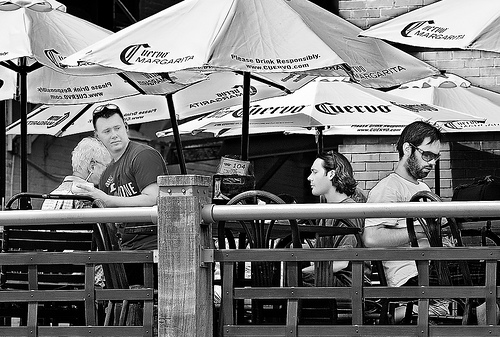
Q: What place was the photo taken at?
A: It was taken at the cafe.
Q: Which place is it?
A: It is a cafe.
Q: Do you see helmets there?
A: No, there are no helmets.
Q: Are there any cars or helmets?
A: No, there are no helmets or cars.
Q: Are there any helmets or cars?
A: No, there are no helmets or cars.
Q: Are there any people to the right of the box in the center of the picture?
A: Yes, there is a person to the right of the box.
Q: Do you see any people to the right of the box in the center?
A: Yes, there is a person to the right of the box.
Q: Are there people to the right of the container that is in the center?
A: Yes, there is a person to the right of the box.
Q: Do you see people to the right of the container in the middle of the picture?
A: Yes, there is a person to the right of the box.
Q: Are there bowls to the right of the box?
A: No, there is a person to the right of the box.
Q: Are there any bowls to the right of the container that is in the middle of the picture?
A: No, there is a person to the right of the box.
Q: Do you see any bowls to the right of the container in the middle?
A: No, there is a person to the right of the box.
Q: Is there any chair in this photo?
A: Yes, there is a chair.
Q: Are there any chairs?
A: Yes, there is a chair.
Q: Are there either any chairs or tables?
A: Yes, there is a chair.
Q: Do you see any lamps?
A: No, there are no lamps.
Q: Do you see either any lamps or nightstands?
A: No, there are no lamps or nightstands.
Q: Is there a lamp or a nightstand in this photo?
A: No, there are no lamps or nightstands.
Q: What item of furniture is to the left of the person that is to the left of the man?
A: The piece of furniture is a chair.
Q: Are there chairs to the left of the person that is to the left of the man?
A: Yes, there is a chair to the left of the person.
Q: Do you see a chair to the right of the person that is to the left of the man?
A: No, the chair is to the left of the person.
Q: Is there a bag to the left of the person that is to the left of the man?
A: No, there is a chair to the left of the person.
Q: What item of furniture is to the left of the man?
A: The piece of furniture is a chair.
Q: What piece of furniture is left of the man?
A: The piece of furniture is a chair.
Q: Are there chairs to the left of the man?
A: Yes, there is a chair to the left of the man.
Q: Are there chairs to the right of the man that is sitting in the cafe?
A: No, the chair is to the left of the man.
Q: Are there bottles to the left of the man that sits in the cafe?
A: No, there is a chair to the left of the man.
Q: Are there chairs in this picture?
A: Yes, there is a chair.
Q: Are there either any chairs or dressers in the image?
A: Yes, there is a chair.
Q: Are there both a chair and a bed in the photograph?
A: No, there is a chair but no beds.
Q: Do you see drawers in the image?
A: No, there are no drawers.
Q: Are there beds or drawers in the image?
A: No, there are no drawers or beds.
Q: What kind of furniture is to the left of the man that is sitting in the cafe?
A: The piece of furniture is a chair.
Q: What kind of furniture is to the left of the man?
A: The piece of furniture is a chair.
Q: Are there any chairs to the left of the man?
A: Yes, there is a chair to the left of the man.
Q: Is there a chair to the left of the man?
A: Yes, there is a chair to the left of the man.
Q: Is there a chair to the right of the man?
A: No, the chair is to the left of the man.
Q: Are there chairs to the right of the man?
A: No, the chair is to the left of the man.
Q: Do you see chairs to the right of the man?
A: No, the chair is to the left of the man.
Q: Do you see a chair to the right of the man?
A: No, the chair is to the left of the man.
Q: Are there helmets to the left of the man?
A: No, there is a chair to the left of the man.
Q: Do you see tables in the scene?
A: Yes, there is a table.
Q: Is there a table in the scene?
A: Yes, there is a table.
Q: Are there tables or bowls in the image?
A: Yes, there is a table.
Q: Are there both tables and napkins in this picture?
A: No, there is a table but no napkins.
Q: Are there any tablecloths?
A: No, there are no tablecloths.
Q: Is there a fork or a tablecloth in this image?
A: No, there are no tablecloths or forks.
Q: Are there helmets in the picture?
A: No, there are no helmets.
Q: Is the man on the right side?
A: Yes, the man is on the right of the image.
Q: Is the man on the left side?
A: No, the man is on the right of the image.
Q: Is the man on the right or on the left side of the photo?
A: The man is on the right of the image.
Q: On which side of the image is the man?
A: The man is on the right of the image.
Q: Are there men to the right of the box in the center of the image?
A: Yes, there is a man to the right of the box.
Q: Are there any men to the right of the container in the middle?
A: Yes, there is a man to the right of the box.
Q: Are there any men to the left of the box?
A: No, the man is to the right of the box.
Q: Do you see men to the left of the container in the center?
A: No, the man is to the right of the box.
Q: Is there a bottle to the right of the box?
A: No, there is a man to the right of the box.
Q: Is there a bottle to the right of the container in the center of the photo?
A: No, there is a man to the right of the box.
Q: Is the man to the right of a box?
A: Yes, the man is to the right of a box.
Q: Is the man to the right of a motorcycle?
A: No, the man is to the right of a box.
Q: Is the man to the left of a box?
A: No, the man is to the right of a box.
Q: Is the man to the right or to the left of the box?
A: The man is to the right of the box.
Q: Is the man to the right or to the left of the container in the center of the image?
A: The man is to the right of the box.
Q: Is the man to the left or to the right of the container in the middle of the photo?
A: The man is to the right of the box.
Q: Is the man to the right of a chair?
A: Yes, the man is to the right of a chair.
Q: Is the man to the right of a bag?
A: No, the man is to the right of a chair.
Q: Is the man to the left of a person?
A: No, the man is to the right of a person.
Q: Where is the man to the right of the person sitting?
A: The man is sitting in the cafe.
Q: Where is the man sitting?
A: The man is sitting in the cafe.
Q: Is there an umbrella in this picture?
A: Yes, there is an umbrella.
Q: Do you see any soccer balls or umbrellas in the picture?
A: Yes, there is an umbrella.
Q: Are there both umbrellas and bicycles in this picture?
A: No, there is an umbrella but no bicycles.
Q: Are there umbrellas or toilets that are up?
A: Yes, the umbrella is up.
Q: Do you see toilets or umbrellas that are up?
A: Yes, the umbrella is up.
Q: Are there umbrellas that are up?
A: Yes, there is an umbrella that is up.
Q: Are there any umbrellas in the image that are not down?
A: Yes, there is an umbrella that is up.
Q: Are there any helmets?
A: No, there are no helmets.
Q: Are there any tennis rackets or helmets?
A: No, there are no helmets or tennis rackets.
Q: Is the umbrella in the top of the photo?
A: Yes, the umbrella is in the top of the image.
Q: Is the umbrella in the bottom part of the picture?
A: No, the umbrella is in the top of the image.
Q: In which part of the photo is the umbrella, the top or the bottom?
A: The umbrella is in the top of the image.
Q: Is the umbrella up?
A: Yes, the umbrella is up.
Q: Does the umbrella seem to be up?
A: Yes, the umbrella is up.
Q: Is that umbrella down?
A: No, the umbrella is up.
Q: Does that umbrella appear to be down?
A: No, the umbrella is up.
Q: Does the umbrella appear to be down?
A: No, the umbrella is up.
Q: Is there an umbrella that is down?
A: No, there is an umbrella but it is up.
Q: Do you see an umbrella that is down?
A: No, there is an umbrella but it is up.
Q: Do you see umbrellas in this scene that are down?
A: No, there is an umbrella but it is up.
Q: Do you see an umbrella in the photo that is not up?
A: No, there is an umbrella but it is up.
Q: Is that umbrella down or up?
A: The umbrella is up.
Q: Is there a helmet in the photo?
A: No, there are no helmets.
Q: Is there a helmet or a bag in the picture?
A: No, there are no helmets or bags.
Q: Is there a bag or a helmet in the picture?
A: No, there are no helmets or bags.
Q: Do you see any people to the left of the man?
A: Yes, there is a person to the left of the man.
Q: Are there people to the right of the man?
A: No, the person is to the left of the man.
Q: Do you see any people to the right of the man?
A: No, the person is to the left of the man.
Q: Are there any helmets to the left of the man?
A: No, there is a person to the left of the man.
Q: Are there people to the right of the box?
A: Yes, there is a person to the right of the box.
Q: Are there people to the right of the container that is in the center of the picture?
A: Yes, there is a person to the right of the box.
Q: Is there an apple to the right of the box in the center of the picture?
A: No, there is a person to the right of the box.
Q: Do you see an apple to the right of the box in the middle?
A: No, there is a person to the right of the box.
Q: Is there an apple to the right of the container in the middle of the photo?
A: No, there is a person to the right of the box.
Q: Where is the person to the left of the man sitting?
A: The person is sitting in the cafe.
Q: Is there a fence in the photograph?
A: Yes, there is a fence.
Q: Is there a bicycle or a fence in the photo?
A: Yes, there is a fence.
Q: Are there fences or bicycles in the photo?
A: Yes, there is a fence.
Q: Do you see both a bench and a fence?
A: No, there is a fence but no benches.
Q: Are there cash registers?
A: No, there are no cash registers.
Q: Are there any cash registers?
A: No, there are no cash registers.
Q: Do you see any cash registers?
A: No, there are no cash registers.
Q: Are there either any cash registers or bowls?
A: No, there are no cash registers or bowls.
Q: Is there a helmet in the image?
A: No, there are no helmets.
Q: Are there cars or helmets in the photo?
A: No, there are no helmets or cars.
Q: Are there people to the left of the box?
A: Yes, there is a person to the left of the box.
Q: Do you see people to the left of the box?
A: Yes, there is a person to the left of the box.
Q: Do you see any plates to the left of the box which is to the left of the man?
A: No, there is a person to the left of the box.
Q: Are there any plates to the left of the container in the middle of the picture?
A: No, there is a person to the left of the box.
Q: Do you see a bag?
A: No, there are no bags.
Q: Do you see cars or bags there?
A: No, there are no bags or cars.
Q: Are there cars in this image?
A: No, there are no cars.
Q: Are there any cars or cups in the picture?
A: No, there are no cars or cups.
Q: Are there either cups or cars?
A: No, there are no cars or cups.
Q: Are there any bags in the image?
A: No, there are no bags.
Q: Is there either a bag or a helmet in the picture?
A: No, there are no bags or helmets.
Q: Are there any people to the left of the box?
A: Yes, there is a person to the left of the box.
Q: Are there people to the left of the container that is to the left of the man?
A: Yes, there is a person to the left of the box.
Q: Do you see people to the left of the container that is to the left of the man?
A: Yes, there is a person to the left of the box.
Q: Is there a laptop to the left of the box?
A: No, there is a person to the left of the box.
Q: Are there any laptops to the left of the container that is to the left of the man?
A: No, there is a person to the left of the box.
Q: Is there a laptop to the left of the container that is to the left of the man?
A: No, there is a person to the left of the box.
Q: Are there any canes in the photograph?
A: No, there are no canes.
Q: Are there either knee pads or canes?
A: No, there are no canes or knee pads.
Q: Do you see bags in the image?
A: No, there are no bags.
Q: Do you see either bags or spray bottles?
A: No, there are no bags or spray bottles.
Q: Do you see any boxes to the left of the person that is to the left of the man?
A: Yes, there is a box to the left of the person.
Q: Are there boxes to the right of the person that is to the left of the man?
A: No, the box is to the left of the person.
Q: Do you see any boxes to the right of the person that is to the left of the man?
A: No, the box is to the left of the person.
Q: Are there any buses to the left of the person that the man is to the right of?
A: No, there is a box to the left of the person.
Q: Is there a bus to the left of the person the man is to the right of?
A: No, there is a box to the left of the person.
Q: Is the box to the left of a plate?
A: No, the box is to the left of a person.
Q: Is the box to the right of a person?
A: No, the box is to the left of a person.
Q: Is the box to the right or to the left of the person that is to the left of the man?
A: The box is to the left of the person.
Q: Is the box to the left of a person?
A: No, the box is to the right of a person.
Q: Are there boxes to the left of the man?
A: Yes, there is a box to the left of the man.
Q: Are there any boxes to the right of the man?
A: No, the box is to the left of the man.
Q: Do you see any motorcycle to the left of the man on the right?
A: No, there is a box to the left of the man.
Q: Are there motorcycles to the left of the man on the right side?
A: No, there is a box to the left of the man.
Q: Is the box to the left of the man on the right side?
A: Yes, the box is to the left of the man.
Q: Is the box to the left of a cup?
A: No, the box is to the left of the man.